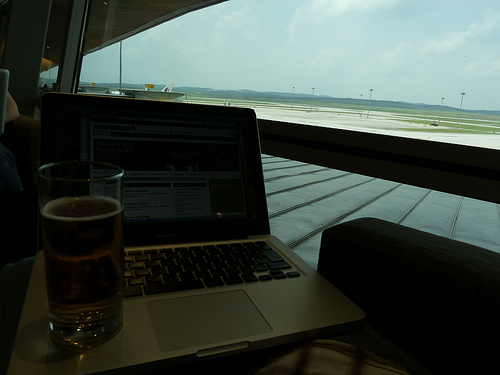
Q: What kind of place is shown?
A: It is an airport.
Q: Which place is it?
A: It is an airport.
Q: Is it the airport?
A: Yes, it is the airport.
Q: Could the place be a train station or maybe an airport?
A: It is an airport.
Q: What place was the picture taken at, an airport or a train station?
A: It was taken at an airport.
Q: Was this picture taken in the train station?
A: No, the picture was taken in the airport.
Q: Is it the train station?
A: No, it is the airport.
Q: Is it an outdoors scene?
A: Yes, it is outdoors.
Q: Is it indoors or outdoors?
A: It is outdoors.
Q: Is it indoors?
A: No, it is outdoors.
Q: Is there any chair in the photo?
A: Yes, there is a chair.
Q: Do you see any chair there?
A: Yes, there is a chair.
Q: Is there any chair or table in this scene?
A: Yes, there is a chair.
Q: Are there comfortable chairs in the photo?
A: Yes, there is a comfortable chair.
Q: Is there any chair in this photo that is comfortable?
A: Yes, there is a chair that is comfortable.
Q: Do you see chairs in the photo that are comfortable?
A: Yes, there is a chair that is comfortable.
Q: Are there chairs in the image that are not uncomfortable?
A: Yes, there is an comfortable chair.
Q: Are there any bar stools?
A: No, there are no bar stools.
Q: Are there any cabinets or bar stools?
A: No, there are no bar stools or cabinets.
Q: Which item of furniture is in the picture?
A: The piece of furniture is a chair.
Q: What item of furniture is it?
A: The piece of furniture is a chair.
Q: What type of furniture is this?
A: This is a chair.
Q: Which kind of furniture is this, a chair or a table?
A: This is a chair.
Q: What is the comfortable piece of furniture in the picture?
A: The piece of furniture is a chair.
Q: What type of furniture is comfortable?
A: The furniture is a chair.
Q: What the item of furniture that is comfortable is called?
A: The piece of furniture is a chair.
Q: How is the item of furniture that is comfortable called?
A: The piece of furniture is a chair.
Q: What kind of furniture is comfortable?
A: The furniture is a chair.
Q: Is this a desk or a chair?
A: This is a chair.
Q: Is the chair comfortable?
A: Yes, the chair is comfortable.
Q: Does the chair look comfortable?
A: Yes, the chair is comfortable.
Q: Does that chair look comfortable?
A: Yes, the chair is comfortable.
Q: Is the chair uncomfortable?
A: No, the chair is comfortable.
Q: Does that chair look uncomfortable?
A: No, the chair is comfortable.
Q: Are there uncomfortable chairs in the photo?
A: No, there is a chair but it is comfortable.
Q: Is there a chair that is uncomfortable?
A: No, there is a chair but it is comfortable.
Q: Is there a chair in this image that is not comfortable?
A: No, there is a chair but it is comfortable.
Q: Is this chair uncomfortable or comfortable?
A: The chair is comfortable.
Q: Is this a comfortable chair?
A: Yes, this is a comfortable chair.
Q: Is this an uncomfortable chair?
A: No, this is a comfortable chair.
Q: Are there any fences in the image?
A: No, there are no fences.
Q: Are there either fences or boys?
A: No, there are no fences or boys.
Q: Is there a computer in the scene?
A: Yes, there is a computer.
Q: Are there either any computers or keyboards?
A: Yes, there is a computer.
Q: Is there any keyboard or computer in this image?
A: Yes, there is a computer.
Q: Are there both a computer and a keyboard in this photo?
A: Yes, there are both a computer and a keyboard.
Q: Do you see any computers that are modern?
A: Yes, there is a modern computer.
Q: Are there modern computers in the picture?
A: Yes, there is a modern computer.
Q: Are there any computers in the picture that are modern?
A: Yes, there is a computer that is modern.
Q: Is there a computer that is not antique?
A: Yes, there is an modern computer.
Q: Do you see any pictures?
A: No, there are no pictures.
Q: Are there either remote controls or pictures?
A: No, there are no pictures or remote controls.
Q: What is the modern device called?
A: The device is a computer.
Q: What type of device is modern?
A: The device is a computer.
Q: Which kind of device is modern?
A: The device is a computer.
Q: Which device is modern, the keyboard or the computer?
A: The computer is modern.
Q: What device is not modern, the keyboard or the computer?
A: The keyboard is not modern.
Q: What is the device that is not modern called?
A: The device is a keyboard.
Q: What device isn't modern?
A: The device is a keyboard.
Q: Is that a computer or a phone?
A: That is a computer.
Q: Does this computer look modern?
A: Yes, the computer is modern.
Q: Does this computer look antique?
A: No, the computer is modern.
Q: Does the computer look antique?
A: No, the computer is modern.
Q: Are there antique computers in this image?
A: No, there is a computer but it is modern.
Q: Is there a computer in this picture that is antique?
A: No, there is a computer but it is modern.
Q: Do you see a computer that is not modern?
A: No, there is a computer but it is modern.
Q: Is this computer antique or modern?
A: The computer is modern.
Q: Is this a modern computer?
A: Yes, this is a modern computer.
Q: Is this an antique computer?
A: No, this is a modern computer.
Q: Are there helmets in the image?
A: No, there are no helmets.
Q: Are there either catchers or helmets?
A: No, there are no helmets or catchers.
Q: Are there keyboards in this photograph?
A: Yes, there is a keyboard.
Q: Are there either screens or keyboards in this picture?
A: Yes, there is a keyboard.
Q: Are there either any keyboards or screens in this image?
A: Yes, there is a keyboard.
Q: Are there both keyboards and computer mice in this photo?
A: No, there is a keyboard but no computer mice.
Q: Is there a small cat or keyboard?
A: Yes, there is a small keyboard.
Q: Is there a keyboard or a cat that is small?
A: Yes, the keyboard is small.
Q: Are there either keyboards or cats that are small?
A: Yes, the keyboard is small.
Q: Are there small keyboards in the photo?
A: Yes, there is a small keyboard.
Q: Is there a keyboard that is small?
A: Yes, there is a keyboard that is small.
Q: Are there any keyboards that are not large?
A: Yes, there is a small keyboard.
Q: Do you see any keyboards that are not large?
A: Yes, there is a small keyboard.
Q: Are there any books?
A: No, there are no books.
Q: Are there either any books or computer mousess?
A: No, there are no books or computer mousess.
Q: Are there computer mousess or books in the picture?
A: No, there are no books or computer mousess.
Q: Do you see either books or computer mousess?
A: No, there are no books or computer mousess.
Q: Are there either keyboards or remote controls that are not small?
A: No, there is a keyboard but it is small.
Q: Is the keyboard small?
A: Yes, the keyboard is small.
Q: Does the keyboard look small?
A: Yes, the keyboard is small.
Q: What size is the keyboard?
A: The keyboard is small.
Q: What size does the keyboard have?
A: The keyboard has small size.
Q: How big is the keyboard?
A: The keyboard is small.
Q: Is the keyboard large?
A: No, the keyboard is small.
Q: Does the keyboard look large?
A: No, the keyboard is small.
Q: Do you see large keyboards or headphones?
A: No, there is a keyboard but it is small.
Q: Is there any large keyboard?
A: No, there is a keyboard but it is small.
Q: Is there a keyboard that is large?
A: No, there is a keyboard but it is small.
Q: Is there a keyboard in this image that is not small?
A: No, there is a keyboard but it is small.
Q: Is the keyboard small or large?
A: The keyboard is small.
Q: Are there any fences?
A: No, there are no fences.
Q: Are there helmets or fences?
A: No, there are no fences or helmets.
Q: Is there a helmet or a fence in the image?
A: No, there are no fences or helmets.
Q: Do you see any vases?
A: No, there are no vases.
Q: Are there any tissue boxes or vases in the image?
A: No, there are no vases or tissue boxes.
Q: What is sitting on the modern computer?
A: The glass is sitting on the computer.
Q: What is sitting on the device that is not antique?
A: The glass is sitting on the computer.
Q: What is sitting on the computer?
A: The glass is sitting on the computer.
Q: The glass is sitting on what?
A: The glass is sitting on the computer.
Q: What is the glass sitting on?
A: The glass is sitting on the computer.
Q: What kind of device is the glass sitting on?
A: The glass is sitting on the computer.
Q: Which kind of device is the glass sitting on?
A: The glass is sitting on the computer.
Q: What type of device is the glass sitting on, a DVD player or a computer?
A: The glass is sitting on a computer.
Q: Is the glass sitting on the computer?
A: Yes, the glass is sitting on the computer.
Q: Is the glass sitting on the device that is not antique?
A: Yes, the glass is sitting on the computer.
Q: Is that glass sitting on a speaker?
A: No, the glass is sitting on the computer.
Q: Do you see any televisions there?
A: No, there are no televisions.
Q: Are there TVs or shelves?
A: No, there are no TVs or shelves.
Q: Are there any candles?
A: No, there are no candles.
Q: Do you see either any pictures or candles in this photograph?
A: No, there are no candles or pictures.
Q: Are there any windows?
A: Yes, there is a window.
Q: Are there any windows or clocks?
A: Yes, there is a window.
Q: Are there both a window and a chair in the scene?
A: Yes, there are both a window and a chair.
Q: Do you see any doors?
A: No, there are no doors.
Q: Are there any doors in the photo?
A: No, there are no doors.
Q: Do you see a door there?
A: No, there are no doors.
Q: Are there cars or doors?
A: No, there are no doors or cars.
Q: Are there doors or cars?
A: No, there are no doors or cars.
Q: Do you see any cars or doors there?
A: No, there are no doors or cars.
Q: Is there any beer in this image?
A: Yes, there is beer.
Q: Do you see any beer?
A: Yes, there is beer.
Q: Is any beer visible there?
A: Yes, there is beer.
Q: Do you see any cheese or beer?
A: Yes, there is beer.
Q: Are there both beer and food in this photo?
A: No, there is beer but no food.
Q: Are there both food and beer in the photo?
A: No, there is beer but no food.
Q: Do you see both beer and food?
A: No, there is beer but no food.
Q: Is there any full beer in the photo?
A: Yes, there is full beer.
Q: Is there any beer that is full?
A: Yes, there is full beer.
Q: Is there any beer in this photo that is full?
A: Yes, there is beer that is full.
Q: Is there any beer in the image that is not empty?
A: Yes, there is full beer.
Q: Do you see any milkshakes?
A: No, there are no milkshakes.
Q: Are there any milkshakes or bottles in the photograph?
A: No, there are no milkshakes or bottles.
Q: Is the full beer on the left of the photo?
A: Yes, the beer is on the left of the image.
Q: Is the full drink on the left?
A: Yes, the beer is on the left of the image.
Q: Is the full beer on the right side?
A: No, the beer is on the left of the image.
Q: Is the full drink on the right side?
A: No, the beer is on the left of the image.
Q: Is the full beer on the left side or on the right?
A: The beer is on the left of the image.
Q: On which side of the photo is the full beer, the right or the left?
A: The beer is on the left of the image.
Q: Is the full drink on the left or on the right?
A: The beer is on the left of the image.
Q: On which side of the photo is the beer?
A: The beer is on the left of the image.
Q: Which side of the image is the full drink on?
A: The beer is on the left of the image.